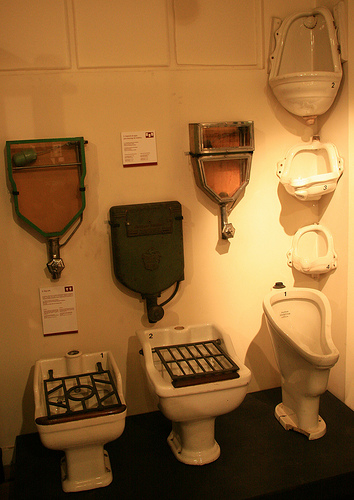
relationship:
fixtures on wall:
[272, 3, 349, 281] [66, 24, 238, 125]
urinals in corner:
[271, 131, 350, 276] [290, 0, 335, 37]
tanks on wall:
[3, 97, 272, 304] [66, 24, 238, 125]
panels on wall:
[0, 0, 273, 72] [66, 24, 238, 125]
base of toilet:
[58, 453, 129, 499] [127, 325, 259, 476]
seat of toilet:
[156, 338, 237, 389] [127, 325, 259, 476]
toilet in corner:
[127, 325, 259, 476] [290, 0, 335, 37]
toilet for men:
[127, 325, 259, 476] [121, 47, 135, 66]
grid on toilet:
[45, 371, 115, 422] [127, 325, 259, 476]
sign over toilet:
[34, 281, 97, 345] [14, 345, 151, 472]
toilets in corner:
[269, 138, 338, 432] [290, 0, 335, 37]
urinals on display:
[271, 131, 350, 276] [73, 112, 348, 442]